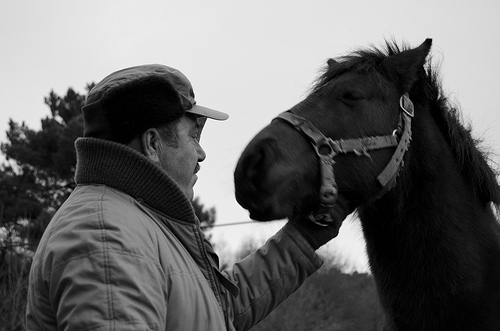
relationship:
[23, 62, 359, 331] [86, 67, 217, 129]
man wearing hat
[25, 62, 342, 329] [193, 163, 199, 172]
man with mustache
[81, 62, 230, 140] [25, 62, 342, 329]
hat on man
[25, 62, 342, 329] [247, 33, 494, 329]
man petting horse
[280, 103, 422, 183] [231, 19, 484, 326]
balck strap on horse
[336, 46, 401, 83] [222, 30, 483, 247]
hair on horse head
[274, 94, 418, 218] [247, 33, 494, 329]
balck strap on horse